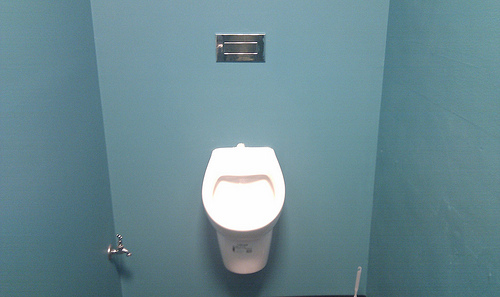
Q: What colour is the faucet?
A: Silver.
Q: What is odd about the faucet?
A: Too low.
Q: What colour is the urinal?
A: White.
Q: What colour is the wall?
A: Blue.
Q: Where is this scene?
A: Stall.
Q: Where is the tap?
A: Wall.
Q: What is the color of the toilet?
A: White.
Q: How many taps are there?
A: 1.